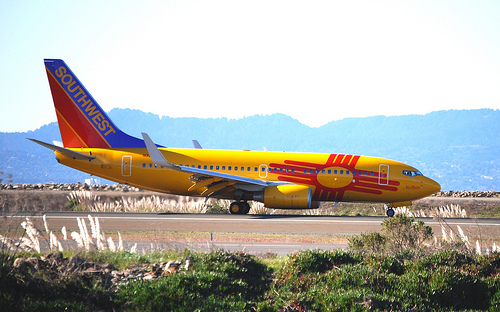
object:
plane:
[24, 58, 442, 218]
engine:
[249, 183, 313, 209]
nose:
[434, 181, 442, 196]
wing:
[141, 130, 299, 197]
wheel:
[228, 201, 251, 215]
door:
[378, 164, 390, 186]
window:
[370, 168, 374, 178]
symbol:
[51, 63, 120, 137]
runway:
[1, 209, 499, 237]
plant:
[83, 193, 226, 215]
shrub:
[383, 211, 438, 262]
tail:
[23, 55, 166, 160]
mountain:
[0, 105, 499, 192]